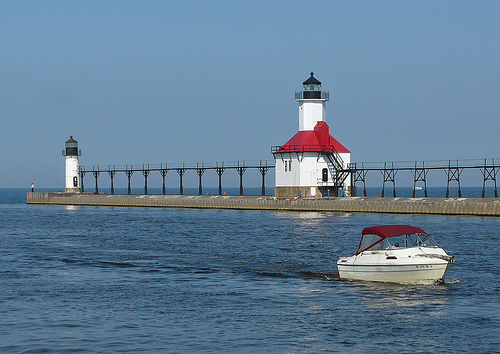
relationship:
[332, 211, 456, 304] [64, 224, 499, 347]
boat on water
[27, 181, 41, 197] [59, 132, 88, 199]
man by lighthouse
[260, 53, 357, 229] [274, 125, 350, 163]
building with roof